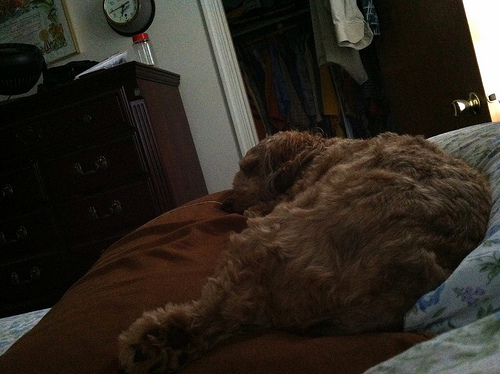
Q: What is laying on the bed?
A: A dog.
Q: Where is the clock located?
A: On wall above dresser.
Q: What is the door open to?
A: The closet.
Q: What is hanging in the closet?
A: Clothing.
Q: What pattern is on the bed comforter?
A: Floral.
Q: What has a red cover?
A: Clear jar on bureau.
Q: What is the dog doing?
A: Sleeping.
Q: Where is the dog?
A: On a bed.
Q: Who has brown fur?
A: A dog.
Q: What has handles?
A: The drawers.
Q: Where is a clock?
A: On the wall.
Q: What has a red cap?
A: A jar.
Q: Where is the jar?
A: On the dresser.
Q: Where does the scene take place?
A: In a bedroom.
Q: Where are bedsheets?
A: On the bed.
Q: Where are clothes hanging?
A: In a closet.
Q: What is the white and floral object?
A: A pillow.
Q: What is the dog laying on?
A: A bed.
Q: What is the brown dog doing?
A: Laying on bed.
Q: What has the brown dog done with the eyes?
A: Closed them.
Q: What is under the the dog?
A: A brown blanket.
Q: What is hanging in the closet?
A: Clothes.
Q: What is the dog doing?
A: Sleeping.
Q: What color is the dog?
A: Brown.